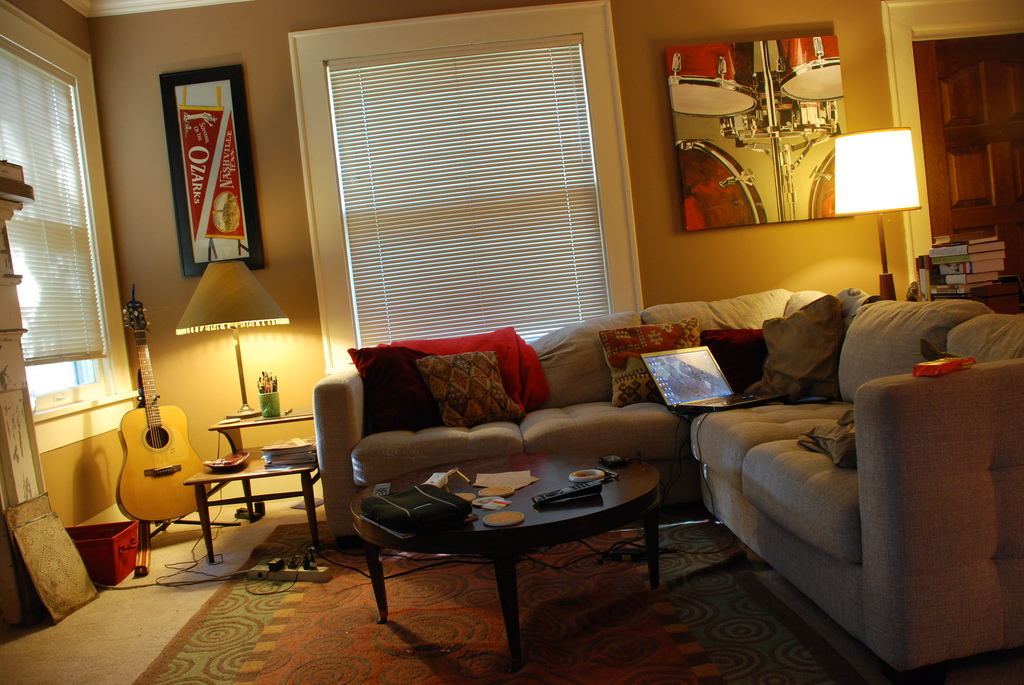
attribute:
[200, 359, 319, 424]
mug — green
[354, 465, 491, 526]
album — black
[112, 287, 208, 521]
guitar — large, brown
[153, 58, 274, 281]
picture frame — long, black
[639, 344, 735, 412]
screen — on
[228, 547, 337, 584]
strip — power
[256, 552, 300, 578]
plugs — black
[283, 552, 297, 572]
plugs — black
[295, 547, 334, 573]
plugs — black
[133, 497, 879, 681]
rug — multicolored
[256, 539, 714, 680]
pattern — swirl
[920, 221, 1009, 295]
books — stack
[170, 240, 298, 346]
lamp — lit, electric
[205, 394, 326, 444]
table — small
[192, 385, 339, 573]
table — wooden, side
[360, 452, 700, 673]
table — round, wooden, coffee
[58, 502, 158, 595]
bin — red, storage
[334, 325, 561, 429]
pillows — colorful, decorative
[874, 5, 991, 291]
door — white, trimmed, wood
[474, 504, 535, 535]
drink coaster — round, cork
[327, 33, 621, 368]
miniblinds — white, closed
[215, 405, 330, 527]
table — small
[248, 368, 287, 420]
vase — small, green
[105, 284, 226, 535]
guitar — acoustic, brown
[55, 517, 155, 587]
storage box — small, red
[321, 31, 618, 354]
window — really big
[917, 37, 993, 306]
door — brown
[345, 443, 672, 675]
coffee table — round, wooden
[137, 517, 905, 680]
carpet — red, green, brown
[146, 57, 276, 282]
picture — framed, black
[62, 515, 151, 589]
container — red, hard, plastic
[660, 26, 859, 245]
painting — square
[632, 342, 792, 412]
laptop — open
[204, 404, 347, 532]
table — small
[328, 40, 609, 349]
blinds — white